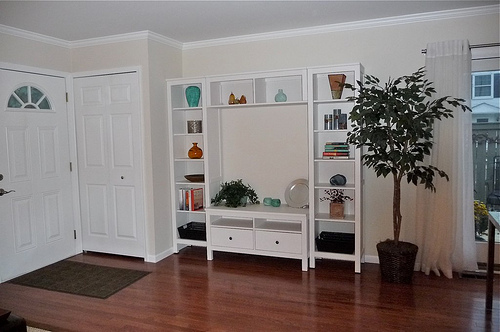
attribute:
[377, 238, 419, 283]
basket — woven, dark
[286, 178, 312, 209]
plate — silver, metallic, white, round, metal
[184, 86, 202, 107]
vase — green, glassy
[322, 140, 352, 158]
books — stacked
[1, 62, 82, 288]
door — white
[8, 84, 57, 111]
window — small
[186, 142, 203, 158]
vase — brown, glassy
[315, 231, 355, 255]
basket — black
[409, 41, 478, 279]
curtains — white, long, sheer, thin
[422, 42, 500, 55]
rod — silver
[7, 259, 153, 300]
rug — small, brown, colored, dark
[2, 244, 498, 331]
floors — cherry colored, wooden, glossy, dark, brown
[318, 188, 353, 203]
plant — green, small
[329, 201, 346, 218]
vase — brown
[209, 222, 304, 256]
cabinets — white, small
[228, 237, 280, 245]
knobs — black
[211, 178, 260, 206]
plant — green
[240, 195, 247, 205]
pot — green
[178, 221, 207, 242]
basket — black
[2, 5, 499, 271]
walls — white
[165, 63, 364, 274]
shelves — white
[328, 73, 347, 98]
pot — tan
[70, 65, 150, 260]
door — white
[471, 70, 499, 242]
window — large